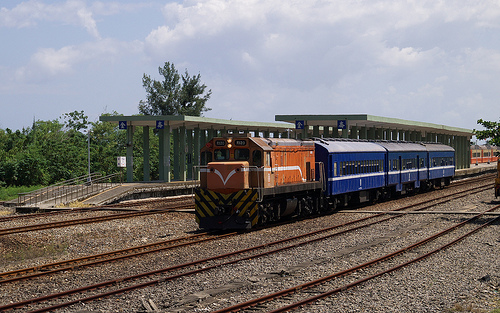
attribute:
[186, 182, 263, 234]
stripes — black , yellow 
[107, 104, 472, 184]
covered platform — train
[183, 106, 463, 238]
passenger car — blue 